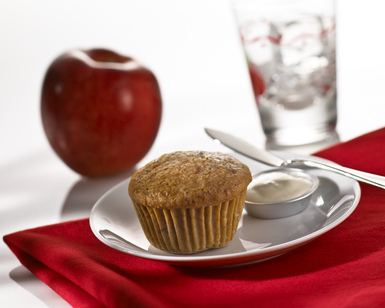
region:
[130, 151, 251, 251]
a brown muffin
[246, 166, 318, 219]
a small silver container of butter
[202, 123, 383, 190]
a knife to spread butter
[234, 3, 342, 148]
a glass of ice water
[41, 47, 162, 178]
a red apple on a table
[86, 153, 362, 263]
round white saucer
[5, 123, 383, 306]
a folded red napkin on a table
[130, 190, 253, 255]
a pleated muffin sleeve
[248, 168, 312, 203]
butter in a silver container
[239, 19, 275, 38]
an ice cube in a glass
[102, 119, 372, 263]
muffin and butter on plate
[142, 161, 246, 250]
bran muffin on plate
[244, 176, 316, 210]
pat of butter on plate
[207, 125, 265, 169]
silver butter knife on plate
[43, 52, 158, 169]
red apple on table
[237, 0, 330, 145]
glass of water with ice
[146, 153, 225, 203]
top of bran muffin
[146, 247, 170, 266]
edge of white plate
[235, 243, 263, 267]
edge of white plate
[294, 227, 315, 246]
edge of white plate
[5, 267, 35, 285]
edge of white place mat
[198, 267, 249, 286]
shadow on red napkin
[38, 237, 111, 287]
grooves in red napkin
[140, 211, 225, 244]
lines in bran muffin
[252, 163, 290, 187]
sour cream in dish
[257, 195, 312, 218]
silver dish holding the sour cream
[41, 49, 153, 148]
juicy red apple on table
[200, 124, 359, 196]
shiny silver knife on plate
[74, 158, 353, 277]
large round white plate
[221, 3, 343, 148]
clear drinking glass filled with ice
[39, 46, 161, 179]
a ripe red apple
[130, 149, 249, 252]
a bran muffin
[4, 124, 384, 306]
a red fabric napkin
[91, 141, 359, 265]
a small white saucer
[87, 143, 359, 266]
a small white plate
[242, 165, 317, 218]
a dish of butter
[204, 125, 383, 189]
a silver knife utensil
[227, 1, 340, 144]
a clear glass of water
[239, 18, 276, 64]
a clear ice cube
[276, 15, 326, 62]
a clear ice cube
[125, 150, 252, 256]
a delicious looking muffin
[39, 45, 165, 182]
a red apple ripe for the taking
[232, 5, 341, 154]
an icy glass of water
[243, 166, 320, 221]
creamy butter for the muffin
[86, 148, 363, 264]
a shiny glass plate for serving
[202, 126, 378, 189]
a shiny silver butter knife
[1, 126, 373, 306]
an elegant red napkin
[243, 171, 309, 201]
butter resting inside a silver tin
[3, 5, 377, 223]
a white table to hold the contents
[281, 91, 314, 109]
ice cube cooling the water